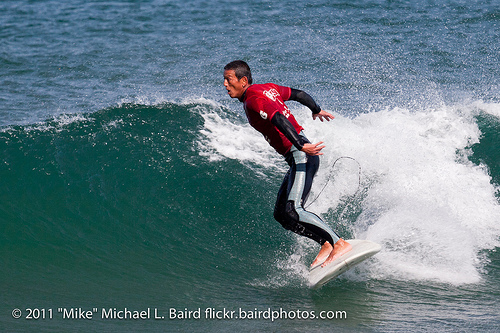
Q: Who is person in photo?
A: Man.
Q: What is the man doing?
A: Surfing.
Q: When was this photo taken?
A: Daytime.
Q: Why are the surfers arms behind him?
A: For balance.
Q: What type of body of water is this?
A: Ocean.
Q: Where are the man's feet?
A: On surfboard.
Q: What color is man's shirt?
A: Red.